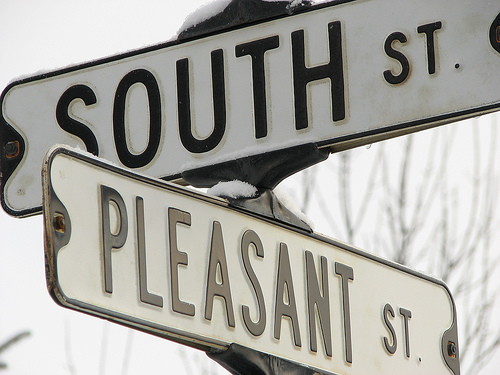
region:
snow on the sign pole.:
[203, 169, 263, 210]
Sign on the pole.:
[35, 138, 464, 372]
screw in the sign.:
[448, 335, 455, 357]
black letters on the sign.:
[87, 176, 415, 368]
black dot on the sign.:
[450, 57, 465, 76]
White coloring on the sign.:
[46, 149, 451, 374]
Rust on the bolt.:
[50, 210, 67, 235]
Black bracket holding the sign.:
[167, 143, 333, 200]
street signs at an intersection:
[1, 4, 499, 374]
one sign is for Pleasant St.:
[38, 137, 463, 374]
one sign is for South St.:
[1, 1, 495, 221]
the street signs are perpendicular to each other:
[1, 0, 498, 374]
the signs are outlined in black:
[1, 3, 499, 369]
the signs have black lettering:
[2, 0, 498, 372]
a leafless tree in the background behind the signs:
[283, 110, 498, 374]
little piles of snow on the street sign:
[165, 0, 332, 202]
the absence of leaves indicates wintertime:
[272, 103, 494, 370]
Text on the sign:
[152, 52, 298, 129]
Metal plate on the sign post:
[141, 55, 341, 140]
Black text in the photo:
[106, 58, 320, 139]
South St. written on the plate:
[89, 22, 455, 113]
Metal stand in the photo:
[219, 168, 306, 205]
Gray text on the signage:
[128, 216, 388, 353]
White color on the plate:
[357, 280, 397, 352]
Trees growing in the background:
[409, 177, 485, 237]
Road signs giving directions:
[179, 23, 315, 350]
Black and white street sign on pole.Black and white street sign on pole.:
[131, 20, 251, 130]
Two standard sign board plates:
[4, 10, 494, 370]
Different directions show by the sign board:
[4, 8, 499, 365]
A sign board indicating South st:
[9, 4, 495, 214]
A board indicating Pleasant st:
[44, 153, 474, 373]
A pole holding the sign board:
[2, 4, 497, 374]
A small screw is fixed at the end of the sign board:
[38, 148, 478, 372]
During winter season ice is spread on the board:
[4, 6, 499, 369]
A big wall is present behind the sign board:
[6, 18, 486, 358]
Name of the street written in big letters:
[8, 22, 486, 372]